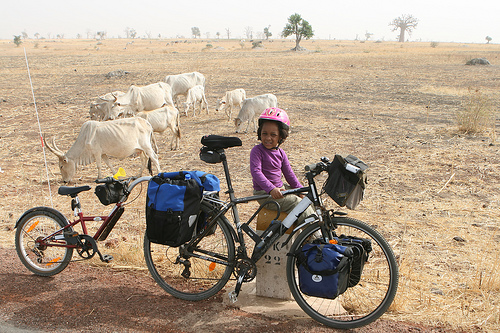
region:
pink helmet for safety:
[256, 107, 291, 130]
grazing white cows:
[42, 72, 277, 179]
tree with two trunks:
[281, 13, 312, 53]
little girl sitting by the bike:
[247, 108, 325, 226]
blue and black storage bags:
[144, 169, 221, 246]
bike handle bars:
[304, 156, 329, 174]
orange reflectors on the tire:
[42, 253, 59, 268]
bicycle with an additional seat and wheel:
[15, 135, 397, 322]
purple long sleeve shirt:
[248, 145, 303, 194]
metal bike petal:
[227, 290, 237, 304]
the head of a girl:
[248, 110, 304, 157]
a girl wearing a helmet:
[249, 105, 321, 156]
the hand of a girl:
[250, 180, 305, 222]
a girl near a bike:
[139, 46, 379, 305]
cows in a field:
[70, 3, 270, 183]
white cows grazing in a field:
[56, 0, 360, 185]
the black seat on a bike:
[153, 108, 257, 197]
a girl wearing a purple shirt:
[171, 68, 388, 204]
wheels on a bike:
[117, 177, 462, 312]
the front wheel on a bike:
[242, 150, 444, 305]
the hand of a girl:
[256, 186, 282, 217]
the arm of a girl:
[236, 149, 301, 203]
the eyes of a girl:
[249, 120, 311, 141]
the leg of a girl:
[248, 182, 328, 237]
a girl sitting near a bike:
[240, 94, 305, 163]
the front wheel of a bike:
[291, 213, 431, 325]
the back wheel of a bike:
[103, 168, 290, 298]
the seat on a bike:
[176, 98, 270, 215]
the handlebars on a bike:
[276, 111, 359, 216]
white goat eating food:
[16, 111, 173, 180]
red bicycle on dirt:
[13, 148, 148, 289]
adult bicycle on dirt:
[123, 123, 433, 331]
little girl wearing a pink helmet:
[248, 100, 313, 155]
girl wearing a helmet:
[241, 98, 311, 197]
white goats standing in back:
[48, 58, 279, 182]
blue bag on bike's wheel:
[289, 237, 368, 309]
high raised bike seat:
[199, 120, 265, 203]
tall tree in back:
[276, 6, 325, 60]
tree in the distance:
[385, 6, 427, 54]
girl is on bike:
[177, 100, 419, 297]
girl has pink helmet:
[251, 113, 292, 130]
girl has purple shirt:
[252, 130, 310, 207]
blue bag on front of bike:
[318, 233, 366, 303]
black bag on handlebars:
[318, 138, 368, 208]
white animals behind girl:
[78, 84, 316, 168]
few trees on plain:
[1, 15, 429, 76]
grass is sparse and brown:
[261, 64, 452, 201]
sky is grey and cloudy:
[411, 5, 461, 36]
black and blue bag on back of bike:
[147, 165, 214, 236]